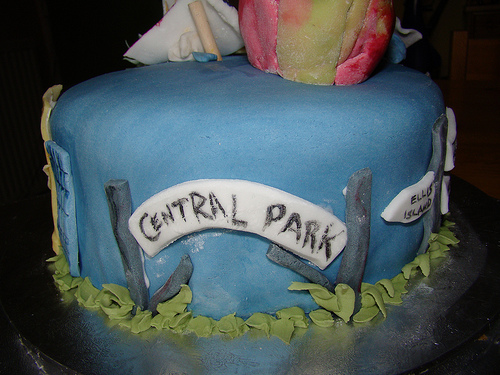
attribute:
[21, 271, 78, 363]
platter — silver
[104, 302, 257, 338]
grass — frosting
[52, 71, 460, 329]
cake — green, blue, decorated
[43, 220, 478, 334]
leaves — green, grassy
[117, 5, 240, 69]
cloth — white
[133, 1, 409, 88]
fondant — yellow, white, rectangle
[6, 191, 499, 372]
metal tray — black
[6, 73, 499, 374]
table — wooden, brown, black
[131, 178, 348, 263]
frosting sign — white, pink, black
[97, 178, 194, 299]
stick — wooden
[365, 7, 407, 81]
toppings — red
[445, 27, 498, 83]
chair — wooden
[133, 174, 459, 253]
words — black, central park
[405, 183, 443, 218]
letters — black